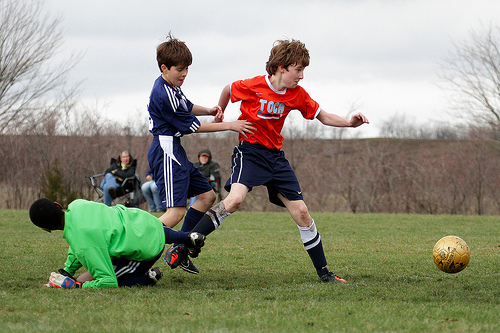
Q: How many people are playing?
A: Three.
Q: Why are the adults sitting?
A: They are watching.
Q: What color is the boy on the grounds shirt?
A: Green.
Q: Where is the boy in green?
A: On the ground.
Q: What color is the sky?
A: Gray.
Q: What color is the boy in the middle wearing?
A: Black.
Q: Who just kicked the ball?
A: The boy in orange.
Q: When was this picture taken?
A: During the day.